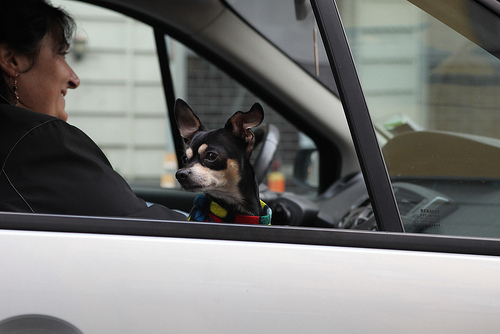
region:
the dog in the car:
[172, 96, 272, 223]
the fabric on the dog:
[187, 192, 272, 224]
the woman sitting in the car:
[0, 0, 190, 222]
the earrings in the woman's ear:
[11, 70, 19, 105]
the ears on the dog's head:
[173, 95, 264, 156]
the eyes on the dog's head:
[182, 150, 220, 162]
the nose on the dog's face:
[174, 168, 191, 181]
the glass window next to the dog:
[312, 0, 499, 237]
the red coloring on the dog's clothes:
[202, 213, 259, 226]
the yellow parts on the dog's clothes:
[208, 197, 265, 217]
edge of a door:
[282, 281, 297, 304]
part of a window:
[376, 197, 379, 269]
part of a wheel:
[265, 155, 272, 177]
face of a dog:
[198, 163, 213, 184]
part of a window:
[417, 147, 434, 184]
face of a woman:
[47, 103, 59, 125]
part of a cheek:
[51, 90, 53, 93]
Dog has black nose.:
[176, 164, 186, 175]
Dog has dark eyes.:
[175, 148, 237, 159]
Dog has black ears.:
[155, 93, 295, 142]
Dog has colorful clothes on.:
[184, 187, 376, 237]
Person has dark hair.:
[13, 15, 56, 45]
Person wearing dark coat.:
[11, 128, 103, 172]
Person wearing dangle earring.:
[6, 65, 33, 116]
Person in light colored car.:
[85, 256, 285, 312]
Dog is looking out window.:
[156, 121, 254, 204]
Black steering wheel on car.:
[252, 110, 284, 188]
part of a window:
[412, 158, 421, 170]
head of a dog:
[221, 161, 236, 183]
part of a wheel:
[262, 160, 274, 185]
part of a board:
[335, 191, 350, 206]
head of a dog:
[198, 162, 220, 199]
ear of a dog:
[247, 110, 258, 125]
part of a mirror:
[294, 158, 306, 180]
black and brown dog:
[171, 99, 267, 221]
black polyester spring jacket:
[0, 103, 187, 224]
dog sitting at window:
[168, 98, 268, 226]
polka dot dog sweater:
[191, 191, 272, 225]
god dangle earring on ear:
[8, 70, 20, 102]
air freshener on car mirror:
[310, 21, 320, 73]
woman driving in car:
[1, 3, 197, 224]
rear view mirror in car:
[290, 2, 312, 21]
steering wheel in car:
[251, 120, 280, 180]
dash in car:
[319, 168, 497, 245]